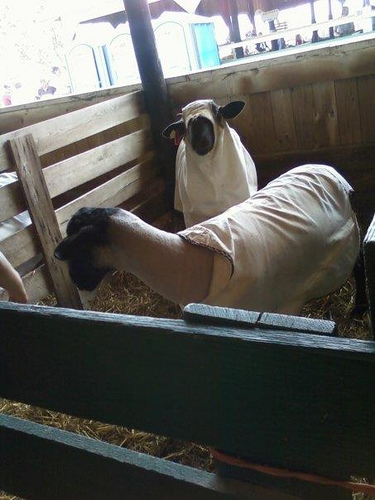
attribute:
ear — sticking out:
[220, 90, 247, 116]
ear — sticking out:
[160, 118, 188, 139]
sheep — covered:
[156, 90, 267, 230]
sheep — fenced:
[159, 95, 261, 213]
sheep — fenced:
[36, 161, 364, 306]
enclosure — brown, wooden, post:
[2, 35, 372, 499]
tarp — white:
[176, 164, 361, 316]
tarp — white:
[173, 97, 258, 215]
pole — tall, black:
[123, 0, 180, 208]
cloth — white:
[205, 188, 353, 309]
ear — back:
[216, 96, 245, 119]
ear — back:
[160, 113, 188, 139]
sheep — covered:
[162, 93, 257, 228]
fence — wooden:
[0, 89, 169, 309]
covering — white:
[169, 140, 368, 313]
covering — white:
[182, 163, 359, 313]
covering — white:
[176, 99, 257, 228]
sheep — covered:
[164, 101, 252, 208]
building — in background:
[58, 1, 374, 64]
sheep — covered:
[50, 161, 366, 325]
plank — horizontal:
[260, 70, 302, 146]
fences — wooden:
[4, 36, 361, 491]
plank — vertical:
[247, 83, 299, 166]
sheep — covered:
[157, 98, 259, 229]